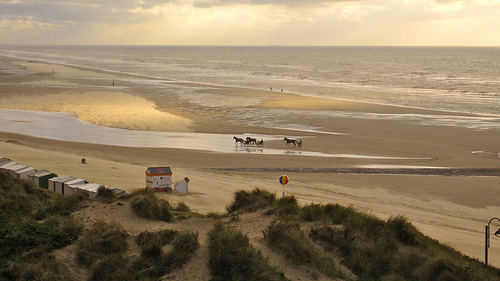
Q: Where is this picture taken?
A: The Ocean.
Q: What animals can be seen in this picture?
A: Horses.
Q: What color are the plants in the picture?
A: Green.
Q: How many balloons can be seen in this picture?
A: One.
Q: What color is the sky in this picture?
A: White.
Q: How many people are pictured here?
A: Zero.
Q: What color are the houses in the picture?
A: White.